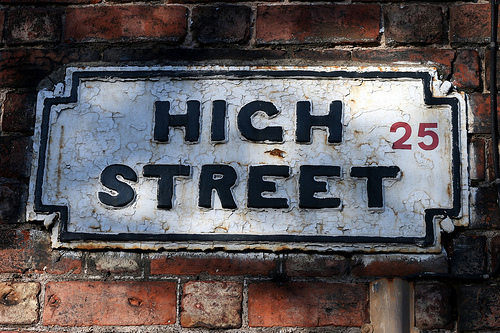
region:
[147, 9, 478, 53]
the building is made of brick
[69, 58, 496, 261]
the sign says High Street 25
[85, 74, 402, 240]
the street name is in black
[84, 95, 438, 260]
the background of the sign is white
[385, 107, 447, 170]
the number 25 is in red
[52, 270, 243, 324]
the bricks appear to be very old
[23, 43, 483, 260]
the sign is trimmed in black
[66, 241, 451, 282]
the sign is made out of metal - it has rust on it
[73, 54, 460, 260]
the sign appears to be quite old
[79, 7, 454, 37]
the bricks are not all the same color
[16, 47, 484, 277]
sign of a street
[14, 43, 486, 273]
sign is white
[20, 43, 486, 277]
sign has black letters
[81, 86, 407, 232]
letters of sign says "High Street"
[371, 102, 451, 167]
number 25 on a sign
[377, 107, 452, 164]
letters are red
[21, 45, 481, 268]
border of sign is black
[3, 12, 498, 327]
a sig over a wall of brick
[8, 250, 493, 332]
wall of brick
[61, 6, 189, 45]
a red brick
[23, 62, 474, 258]
a white sign on the wall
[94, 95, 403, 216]
black writing on the sign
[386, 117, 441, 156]
red numbers on the sign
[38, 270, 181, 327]
a red brick in the wall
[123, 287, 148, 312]
a hole in the brick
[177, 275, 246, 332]
a white brick in the wall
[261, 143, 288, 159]
a section of chipped paint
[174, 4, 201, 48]
gray caulk between the bricks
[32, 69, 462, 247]
a black border around the sign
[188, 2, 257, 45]
a black brick in the wall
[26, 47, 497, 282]
a black and white street sign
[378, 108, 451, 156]
red numbers on a white sign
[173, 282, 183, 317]
gray cement in the crack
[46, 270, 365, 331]
red bricks in a wall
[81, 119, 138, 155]
old cracked white paint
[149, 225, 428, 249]
black trim on white sign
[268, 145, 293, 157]
a rust stain on the sign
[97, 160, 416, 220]
black letters on the sign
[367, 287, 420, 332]
a missing brick in the wall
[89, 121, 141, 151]
chipping white paint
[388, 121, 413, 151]
number two painted in red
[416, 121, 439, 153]
number five painted red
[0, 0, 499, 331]
red rustic brick wall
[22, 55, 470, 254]
aged red, white and blue sign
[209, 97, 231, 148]
letter I painted in blue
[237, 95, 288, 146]
letter G painted in blue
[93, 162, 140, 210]
letter S painted in blue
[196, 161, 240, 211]
letter R painted in blue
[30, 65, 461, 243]
blue decorative line design on sign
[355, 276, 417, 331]
rusty metal pipe